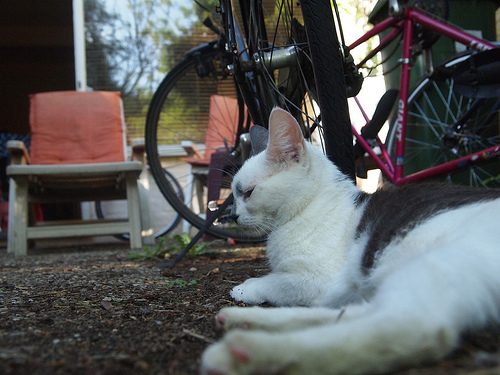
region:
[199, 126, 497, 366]
Black and white cat laying on ground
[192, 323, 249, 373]
Pink toes on paw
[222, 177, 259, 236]
Black nose on cat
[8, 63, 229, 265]
Red cushion chair with wood frame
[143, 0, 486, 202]
Parked bicycle on ground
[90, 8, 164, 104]
Reflection of tree on window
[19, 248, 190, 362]
Dirt and rock ground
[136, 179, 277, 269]
Kickstand on the bike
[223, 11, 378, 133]
Spokes on a bike wheel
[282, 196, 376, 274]
Short hair on the cat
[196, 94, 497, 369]
a white and black cat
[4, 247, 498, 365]
dirt ground under a cat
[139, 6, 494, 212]
a dark pink bicycle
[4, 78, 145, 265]
a white wood chair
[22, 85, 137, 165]
an orange cushion in a chair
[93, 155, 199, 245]
a spare bicycle wheel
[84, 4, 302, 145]
blinds in a window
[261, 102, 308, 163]
the ear of a cat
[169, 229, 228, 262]
a weed in the dirt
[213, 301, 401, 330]
the white foot of a cat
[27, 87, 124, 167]
Mattress is orange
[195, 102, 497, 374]
Cat is black and white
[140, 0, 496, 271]
Bike is magenta pink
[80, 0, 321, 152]
Large window behind mattress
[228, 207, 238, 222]
Nose is black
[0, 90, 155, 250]
Chair is wooden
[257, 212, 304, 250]
Whisker is long and white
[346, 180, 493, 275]
Black fur on white cat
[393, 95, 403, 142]
GIANT logo is white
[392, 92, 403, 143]
GIANT logo on bike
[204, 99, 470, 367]
the cat is sitting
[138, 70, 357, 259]
the cat is looking down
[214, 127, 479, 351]
the cat is white and black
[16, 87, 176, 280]
the chair is made of wood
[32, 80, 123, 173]
the cushion is yellow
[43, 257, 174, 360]
the ground is made of soil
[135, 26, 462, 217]
the bike is parked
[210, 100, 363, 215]
the ears are up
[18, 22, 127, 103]
the line is white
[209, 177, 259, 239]
the nose is black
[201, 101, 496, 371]
a cat laying on the ground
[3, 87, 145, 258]
a chair with orange cushions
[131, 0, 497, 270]
two bicycles parked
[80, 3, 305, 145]
a window reflecting trees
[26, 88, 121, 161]
orange chair cushion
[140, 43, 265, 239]
bicycle wheel turned to the left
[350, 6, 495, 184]
pink frame of a bicycle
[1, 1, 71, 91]
siding of a house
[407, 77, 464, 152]
bicycle wheel spokes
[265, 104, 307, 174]
the ear of the cat